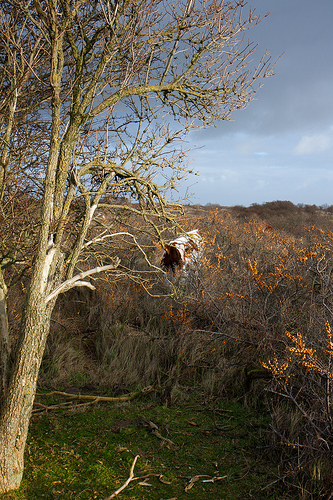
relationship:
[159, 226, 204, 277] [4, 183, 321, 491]
cow in bushes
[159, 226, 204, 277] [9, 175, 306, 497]
cow in bushes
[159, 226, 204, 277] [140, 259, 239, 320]
cow in bushes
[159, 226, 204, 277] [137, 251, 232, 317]
cow in bushes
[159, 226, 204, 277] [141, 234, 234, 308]
cow in bushes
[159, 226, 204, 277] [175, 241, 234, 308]
cow in bushes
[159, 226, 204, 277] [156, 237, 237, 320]
cow in bushes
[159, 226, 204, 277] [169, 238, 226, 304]
cow in bushes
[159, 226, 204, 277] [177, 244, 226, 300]
cow in bushes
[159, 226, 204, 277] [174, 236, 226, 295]
cow in bushes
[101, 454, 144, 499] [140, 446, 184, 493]
branch on ground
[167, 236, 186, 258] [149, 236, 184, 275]
patch on cow's face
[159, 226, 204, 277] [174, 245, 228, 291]
cow standing in bush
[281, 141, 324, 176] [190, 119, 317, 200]
clouds in sky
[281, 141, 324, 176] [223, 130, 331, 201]
clouds in sky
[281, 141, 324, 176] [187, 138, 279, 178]
clouds in sky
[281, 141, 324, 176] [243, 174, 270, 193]
clouds in clouds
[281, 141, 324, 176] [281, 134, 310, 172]
clouds in sky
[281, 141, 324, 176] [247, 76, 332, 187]
clouds in sky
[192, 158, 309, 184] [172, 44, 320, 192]
white clouds in blue sky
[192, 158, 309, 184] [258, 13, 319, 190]
white clouds in blue sky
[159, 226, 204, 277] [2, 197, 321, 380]
cow in forest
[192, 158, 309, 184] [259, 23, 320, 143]
white clouds in blue sky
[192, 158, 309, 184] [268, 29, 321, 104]
white clouds in blue sky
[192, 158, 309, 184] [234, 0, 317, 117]
white clouds in blue sky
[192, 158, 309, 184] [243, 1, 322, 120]
white clouds in blue sky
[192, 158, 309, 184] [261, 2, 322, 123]
white clouds in blue sky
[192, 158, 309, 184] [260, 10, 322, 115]
white clouds in blue sky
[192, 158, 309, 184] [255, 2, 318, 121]
white clouds in blue sky